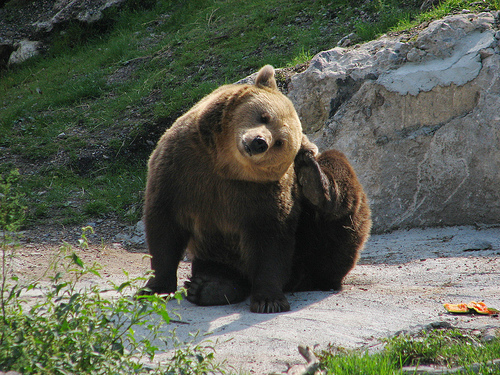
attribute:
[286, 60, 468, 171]
rock — large, gray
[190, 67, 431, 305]
bear — large, brown colored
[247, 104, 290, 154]
eyes — bear's eyes, black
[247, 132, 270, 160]
nose — black, bear's nose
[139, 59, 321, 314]
bear — sitting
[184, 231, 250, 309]
leg — bear leg, large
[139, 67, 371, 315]
bear — fuzzy, brown, brown colored, large, scratching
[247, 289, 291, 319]
paw — bear paw, large, brown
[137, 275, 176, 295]
paw — bear paw, large, brown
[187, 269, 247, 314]
paw — bear paw, large, brown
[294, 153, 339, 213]
paw — bear paw, large, brown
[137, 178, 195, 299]
leg — bear leg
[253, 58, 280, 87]
ear — bear's ear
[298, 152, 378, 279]
bear leg — large, brown colored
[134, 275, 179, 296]
bear paw — brown colored, large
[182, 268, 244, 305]
bear paw — brown colored, large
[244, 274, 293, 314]
bear paw — brown colored, large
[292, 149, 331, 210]
bear paw — brown colored, large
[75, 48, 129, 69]
grass — green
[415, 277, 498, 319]
object — orange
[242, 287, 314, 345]
paw — bear paw